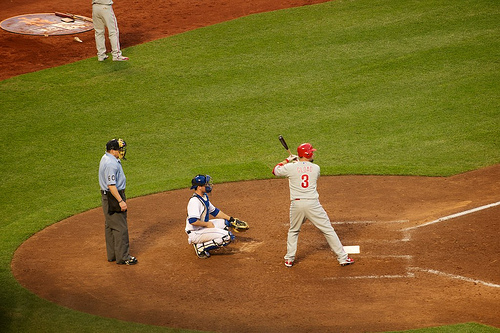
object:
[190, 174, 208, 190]
helmet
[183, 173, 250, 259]
catcher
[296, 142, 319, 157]
helmet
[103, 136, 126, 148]
cap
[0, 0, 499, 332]
field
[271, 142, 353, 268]
people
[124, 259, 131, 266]
cleats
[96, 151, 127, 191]
shirt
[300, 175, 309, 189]
number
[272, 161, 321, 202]
jersey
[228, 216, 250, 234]
glove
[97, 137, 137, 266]
umpire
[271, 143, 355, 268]
batter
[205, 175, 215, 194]
facemask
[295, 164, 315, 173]
writing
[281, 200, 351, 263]
pants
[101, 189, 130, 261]
slacks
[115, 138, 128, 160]
shield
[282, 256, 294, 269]
shoes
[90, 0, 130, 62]
person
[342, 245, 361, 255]
base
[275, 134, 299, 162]
bat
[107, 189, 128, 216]
apron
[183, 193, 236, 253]
uniform